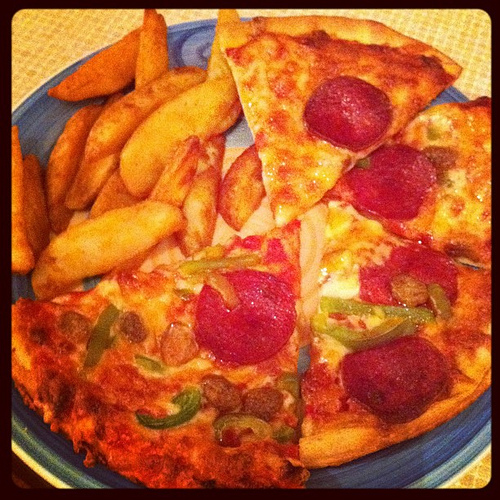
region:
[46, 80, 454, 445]
pizza and fries on a plate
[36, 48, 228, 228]
these fries are golden brown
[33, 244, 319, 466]
the pizza has pepperoni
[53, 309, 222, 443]
the pizza has peppers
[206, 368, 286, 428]
the sausage is on the pizza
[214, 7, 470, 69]
a golden crust on the pizza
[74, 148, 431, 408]
this is a meal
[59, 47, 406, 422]
someone ate a slice of this pizza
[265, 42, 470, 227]
two slices of pepperoni pizza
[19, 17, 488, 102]
the pizza and fries is on a yellow table cloth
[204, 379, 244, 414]
topping on the pizza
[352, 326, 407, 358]
topping on the pizza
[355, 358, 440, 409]
topping on the pizza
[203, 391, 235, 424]
topping on the pizza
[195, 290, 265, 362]
topping on the pizza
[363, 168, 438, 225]
topping on the pizza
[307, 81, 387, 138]
topping on the pizza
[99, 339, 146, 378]
topping on the pizza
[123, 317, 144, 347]
topping on the pizza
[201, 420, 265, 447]
topping on the pizza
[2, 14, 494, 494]
four slices of pizza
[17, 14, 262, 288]
French fries on a plate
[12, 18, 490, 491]
a round blue plate with food on it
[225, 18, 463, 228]
piece of pizza with one slice of pepperoni on it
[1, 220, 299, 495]
bottom left piece of pizza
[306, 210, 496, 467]
bottom right piece of pizza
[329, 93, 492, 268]
middle piece of pizza on right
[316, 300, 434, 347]
piece of bell pepper on bottom right slice of pizza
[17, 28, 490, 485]
four slices of pizza and some fries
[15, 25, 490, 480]
a pepperoni and bell pepper pizza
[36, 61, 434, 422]
a photo of a meal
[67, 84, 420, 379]
this is dish for a person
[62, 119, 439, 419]
pizza and fries is on the plate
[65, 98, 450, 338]
pepporoni dish on the plate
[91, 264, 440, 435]
green peppers on pizza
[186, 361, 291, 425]
sausage on the pizza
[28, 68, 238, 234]
crispy fies with no ketchup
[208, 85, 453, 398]
pepperoni on the pizza pie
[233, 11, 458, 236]
this pizza is well done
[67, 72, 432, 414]
this is a meal for a person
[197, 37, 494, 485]
pizza on round plate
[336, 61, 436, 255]
red pepperoni on pizza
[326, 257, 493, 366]
green peppers on pizza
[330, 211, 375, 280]
yellow cheese on pizza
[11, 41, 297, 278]
brown french fries on plate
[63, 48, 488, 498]
blue border on plate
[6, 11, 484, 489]
plate on yellow table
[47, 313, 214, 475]
dark brown pizza crust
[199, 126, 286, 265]
white inner part of plate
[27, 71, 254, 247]
dark brown french fries